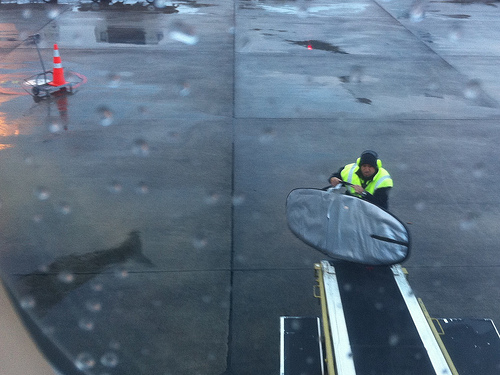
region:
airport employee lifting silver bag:
[277, 145, 492, 374]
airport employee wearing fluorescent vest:
[329, 145, 396, 207]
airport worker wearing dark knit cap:
[326, 146, 396, 209]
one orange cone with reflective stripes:
[40, 35, 75, 96]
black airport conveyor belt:
[313, 250, 441, 372]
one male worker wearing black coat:
[322, 145, 401, 215]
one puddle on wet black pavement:
[241, 7, 406, 100]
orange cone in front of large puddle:
[28, 16, 183, 91]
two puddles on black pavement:
[80, 16, 362, 66]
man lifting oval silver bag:
[272, 143, 417, 270]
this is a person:
[303, 137, 413, 233]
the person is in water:
[155, 299, 220, 361]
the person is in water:
[69, 51, 211, 203]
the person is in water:
[301, 131, 454, 301]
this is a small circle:
[67, 305, 98, 337]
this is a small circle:
[104, 335, 121, 372]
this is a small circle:
[184, 210, 220, 270]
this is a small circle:
[107, 171, 126, 207]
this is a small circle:
[459, 210, 490, 250]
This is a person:
[301, 111, 429, 248]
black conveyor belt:
[310, 253, 455, 373]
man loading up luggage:
[322, 140, 397, 226]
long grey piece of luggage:
[281, 177, 417, 269]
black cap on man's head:
[358, 148, 377, 170]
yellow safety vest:
[340, 158, 396, 204]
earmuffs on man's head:
[354, 147, 384, 169]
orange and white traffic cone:
[44, 36, 66, 89]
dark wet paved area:
[1, 2, 496, 374]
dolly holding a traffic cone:
[25, 30, 76, 103]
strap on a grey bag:
[322, 178, 372, 205]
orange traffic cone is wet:
[48, 43, 69, 88]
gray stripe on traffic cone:
[51, 50, 60, 57]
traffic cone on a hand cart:
[26, 33, 83, 100]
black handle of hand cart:
[23, 31, 49, 82]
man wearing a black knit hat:
[328, 150, 392, 209]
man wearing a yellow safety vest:
[341, 152, 393, 198]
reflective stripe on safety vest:
[346, 159, 355, 184]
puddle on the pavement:
[297, 39, 349, 61]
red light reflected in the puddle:
[304, 43, 311, 48]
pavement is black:
[0, 0, 499, 371]